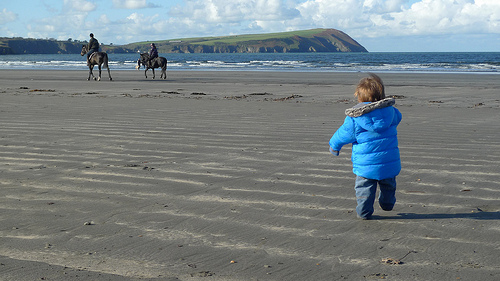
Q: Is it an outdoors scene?
A: Yes, it is outdoors.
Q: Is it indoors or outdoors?
A: It is outdoors.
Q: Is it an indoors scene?
A: No, it is outdoors.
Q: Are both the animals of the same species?
A: Yes, all the animals are horses.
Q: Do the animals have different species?
A: No, all the animals are horses.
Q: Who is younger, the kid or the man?
A: The kid is younger than the man.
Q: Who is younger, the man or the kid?
A: The kid is younger than the man.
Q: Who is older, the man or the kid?
A: The man is older than the kid.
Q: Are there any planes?
A: No, there are no planes.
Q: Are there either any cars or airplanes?
A: No, there are no airplanes or cars.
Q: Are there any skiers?
A: No, there are no skiers.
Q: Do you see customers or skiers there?
A: No, there are no skiers or customers.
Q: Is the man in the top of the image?
A: Yes, the man is in the top of the image.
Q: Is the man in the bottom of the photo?
A: No, the man is in the top of the image.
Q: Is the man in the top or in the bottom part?
A: The man is in the top of the image.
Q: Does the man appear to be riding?
A: Yes, the man is riding.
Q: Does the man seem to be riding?
A: Yes, the man is riding.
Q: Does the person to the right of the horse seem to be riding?
A: Yes, the man is riding.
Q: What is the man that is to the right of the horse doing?
A: The man is riding.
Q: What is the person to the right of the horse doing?
A: The man is riding.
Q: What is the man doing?
A: The man is riding.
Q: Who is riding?
A: The man is riding.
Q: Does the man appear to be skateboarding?
A: No, the man is riding.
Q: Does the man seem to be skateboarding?
A: No, the man is riding.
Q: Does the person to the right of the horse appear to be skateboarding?
A: No, the man is riding.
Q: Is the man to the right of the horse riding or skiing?
A: The man is riding.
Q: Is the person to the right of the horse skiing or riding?
A: The man is riding.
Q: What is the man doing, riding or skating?
A: The man is riding.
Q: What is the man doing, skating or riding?
A: The man is riding.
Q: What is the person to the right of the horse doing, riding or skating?
A: The man is riding.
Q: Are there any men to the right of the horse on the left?
A: Yes, there is a man to the right of the horse.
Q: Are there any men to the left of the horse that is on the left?
A: No, the man is to the right of the horse.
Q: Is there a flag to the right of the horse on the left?
A: No, there is a man to the right of the horse.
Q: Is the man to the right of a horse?
A: Yes, the man is to the right of a horse.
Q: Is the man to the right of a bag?
A: No, the man is to the right of a horse.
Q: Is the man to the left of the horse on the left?
A: No, the man is to the right of the horse.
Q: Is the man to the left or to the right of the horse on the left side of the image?
A: The man is to the right of the horse.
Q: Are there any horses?
A: Yes, there is a horse.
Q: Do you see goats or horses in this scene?
A: Yes, there is a horse.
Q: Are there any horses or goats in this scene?
A: Yes, there is a horse.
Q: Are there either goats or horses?
A: Yes, there is a horse.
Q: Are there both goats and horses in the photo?
A: No, there is a horse but no goats.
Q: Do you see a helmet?
A: No, there are no helmets.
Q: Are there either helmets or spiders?
A: No, there are no helmets or spiders.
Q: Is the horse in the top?
A: Yes, the horse is in the top of the image.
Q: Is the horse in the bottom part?
A: No, the horse is in the top of the image.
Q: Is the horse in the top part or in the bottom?
A: The horse is in the top of the image.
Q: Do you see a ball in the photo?
A: No, there are no balls.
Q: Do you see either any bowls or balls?
A: No, there are no balls or bowls.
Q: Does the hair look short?
A: Yes, the hair is short.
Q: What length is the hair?
A: The hair is short.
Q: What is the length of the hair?
A: The hair is short.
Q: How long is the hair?
A: The hair is short.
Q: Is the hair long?
A: No, the hair is short.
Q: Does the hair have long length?
A: No, the hair is short.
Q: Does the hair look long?
A: No, the hair is short.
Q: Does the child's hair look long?
A: No, the hair is short.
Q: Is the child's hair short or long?
A: The hair is short.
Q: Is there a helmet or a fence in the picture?
A: No, there are no helmets or fences.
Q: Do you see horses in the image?
A: Yes, there is a horse.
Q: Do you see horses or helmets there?
A: Yes, there is a horse.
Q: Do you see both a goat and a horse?
A: No, there is a horse but no goats.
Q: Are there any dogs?
A: No, there are no dogs.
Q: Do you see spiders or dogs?
A: No, there are no dogs or spiders.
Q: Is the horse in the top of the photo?
A: Yes, the horse is in the top of the image.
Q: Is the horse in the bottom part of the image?
A: No, the horse is in the top of the image.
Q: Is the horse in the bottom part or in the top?
A: The horse is in the top of the image.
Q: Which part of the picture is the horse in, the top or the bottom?
A: The horse is in the top of the image.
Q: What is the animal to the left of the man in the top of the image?
A: The animal is a horse.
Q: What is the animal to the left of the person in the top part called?
A: The animal is a horse.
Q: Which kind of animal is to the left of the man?
A: The animal is a horse.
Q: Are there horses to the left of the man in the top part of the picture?
A: Yes, there is a horse to the left of the man.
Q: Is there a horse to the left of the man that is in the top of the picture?
A: Yes, there is a horse to the left of the man.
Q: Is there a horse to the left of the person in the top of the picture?
A: Yes, there is a horse to the left of the man.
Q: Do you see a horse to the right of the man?
A: No, the horse is to the left of the man.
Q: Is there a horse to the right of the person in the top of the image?
A: No, the horse is to the left of the man.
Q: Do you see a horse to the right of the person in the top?
A: No, the horse is to the left of the man.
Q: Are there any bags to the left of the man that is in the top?
A: No, there is a horse to the left of the man.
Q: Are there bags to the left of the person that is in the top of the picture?
A: No, there is a horse to the left of the man.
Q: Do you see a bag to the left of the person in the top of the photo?
A: No, there is a horse to the left of the man.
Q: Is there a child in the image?
A: Yes, there is a child.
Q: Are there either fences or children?
A: Yes, there is a child.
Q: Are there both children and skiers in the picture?
A: No, there is a child but no skiers.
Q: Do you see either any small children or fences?
A: Yes, there is a small child.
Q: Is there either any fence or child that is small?
A: Yes, the child is small.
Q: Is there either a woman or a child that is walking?
A: Yes, the child is walking.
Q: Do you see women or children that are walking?
A: Yes, the child is walking.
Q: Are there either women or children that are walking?
A: Yes, the child is walking.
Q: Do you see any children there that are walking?
A: Yes, there is a child that is walking.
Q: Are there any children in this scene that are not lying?
A: Yes, there is a child that is walking.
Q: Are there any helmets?
A: No, there are no helmets.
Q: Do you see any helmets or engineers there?
A: No, there are no helmets or engineers.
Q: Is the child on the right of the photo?
A: Yes, the child is on the right of the image.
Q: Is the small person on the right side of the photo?
A: Yes, the child is on the right of the image.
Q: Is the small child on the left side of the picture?
A: No, the child is on the right of the image.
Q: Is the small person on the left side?
A: No, the child is on the right of the image.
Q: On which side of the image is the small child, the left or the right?
A: The child is on the right of the image.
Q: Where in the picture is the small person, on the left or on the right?
A: The child is on the right of the image.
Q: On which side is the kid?
A: The kid is on the right of the image.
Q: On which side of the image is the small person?
A: The kid is on the right of the image.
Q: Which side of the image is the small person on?
A: The kid is on the right of the image.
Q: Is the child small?
A: Yes, the child is small.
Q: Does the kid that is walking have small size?
A: Yes, the kid is small.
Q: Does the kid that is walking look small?
A: Yes, the kid is small.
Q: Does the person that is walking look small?
A: Yes, the kid is small.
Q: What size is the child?
A: The child is small.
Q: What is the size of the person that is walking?
A: The child is small.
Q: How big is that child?
A: The child is small.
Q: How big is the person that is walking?
A: The child is small.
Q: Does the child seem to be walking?
A: Yes, the child is walking.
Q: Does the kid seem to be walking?
A: Yes, the kid is walking.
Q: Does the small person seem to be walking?
A: Yes, the kid is walking.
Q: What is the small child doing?
A: The child is walking.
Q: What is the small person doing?
A: The child is walking.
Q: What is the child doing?
A: The child is walking.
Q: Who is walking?
A: The child is walking.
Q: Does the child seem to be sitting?
A: No, the child is walking.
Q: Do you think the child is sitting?
A: No, the child is walking.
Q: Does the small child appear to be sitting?
A: No, the kid is walking.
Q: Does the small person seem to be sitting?
A: No, the kid is walking.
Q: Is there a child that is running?
A: No, there is a child but he is walking.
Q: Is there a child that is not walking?
A: No, there is a child but he is walking.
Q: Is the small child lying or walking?
A: The kid is walking.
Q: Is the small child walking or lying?
A: The kid is walking.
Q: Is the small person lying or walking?
A: The kid is walking.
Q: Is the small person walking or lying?
A: The kid is walking.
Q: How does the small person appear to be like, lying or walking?
A: The kid is walking.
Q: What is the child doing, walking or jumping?
A: The child is walking.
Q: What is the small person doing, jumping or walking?
A: The child is walking.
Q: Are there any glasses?
A: No, there are no glasses.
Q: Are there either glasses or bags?
A: No, there are no glasses or bags.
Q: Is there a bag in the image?
A: No, there are no bags.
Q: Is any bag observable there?
A: No, there are no bags.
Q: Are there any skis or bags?
A: No, there are no bags or skis.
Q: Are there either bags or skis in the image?
A: No, there are no bags or skis.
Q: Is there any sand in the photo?
A: Yes, there is sand.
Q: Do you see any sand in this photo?
A: Yes, there is sand.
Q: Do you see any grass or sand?
A: Yes, there is sand.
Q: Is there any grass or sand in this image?
A: Yes, there is sand.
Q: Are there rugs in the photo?
A: No, there are no rugs.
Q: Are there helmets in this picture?
A: No, there are no helmets.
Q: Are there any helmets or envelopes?
A: No, there are no helmets or envelopes.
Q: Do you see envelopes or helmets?
A: No, there are no helmets or envelopes.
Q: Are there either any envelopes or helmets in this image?
A: No, there are no helmets or envelopes.